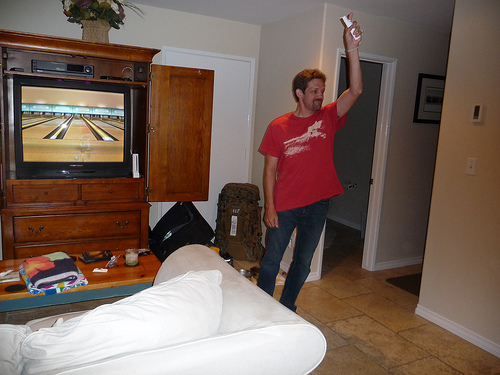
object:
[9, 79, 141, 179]
entertainment center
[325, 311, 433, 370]
floor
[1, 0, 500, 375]
room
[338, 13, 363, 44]
wii remote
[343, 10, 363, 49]
hand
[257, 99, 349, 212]
shirt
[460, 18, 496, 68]
wall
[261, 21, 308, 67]
wall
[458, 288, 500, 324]
wall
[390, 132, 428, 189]
wall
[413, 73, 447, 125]
picture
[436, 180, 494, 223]
wall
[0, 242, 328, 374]
couch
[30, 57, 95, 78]
player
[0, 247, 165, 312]
table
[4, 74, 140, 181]
fence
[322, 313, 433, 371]
floors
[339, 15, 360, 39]
controller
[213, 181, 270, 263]
luggage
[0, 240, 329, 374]
sofa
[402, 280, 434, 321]
corner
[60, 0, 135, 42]
flowers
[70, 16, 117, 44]
pot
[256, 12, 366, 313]
he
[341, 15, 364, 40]
remote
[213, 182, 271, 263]
suitcase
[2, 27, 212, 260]
cabinet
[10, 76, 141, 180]
television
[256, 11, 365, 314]
man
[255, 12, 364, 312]
person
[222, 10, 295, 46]
corner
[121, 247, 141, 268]
candle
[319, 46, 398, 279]
door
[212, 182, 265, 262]
item